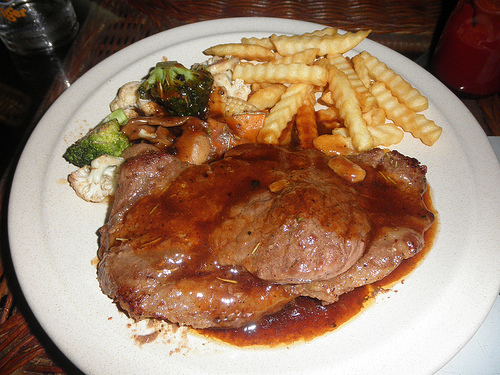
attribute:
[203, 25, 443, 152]
fries — a serving, french, crinkled, sauced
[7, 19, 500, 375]
plate — glossy white, very white, very shiny, bright, very bright, shiny white, bright white, white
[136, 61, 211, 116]
broccoli — grilled, in sauce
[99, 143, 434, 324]
meat — in sauce, steak, over sauce, juicy, sliced, covered in gravy, sauced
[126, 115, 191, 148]
mushroom — grilled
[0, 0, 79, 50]
glass — empty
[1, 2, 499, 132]
table — brown, wicker